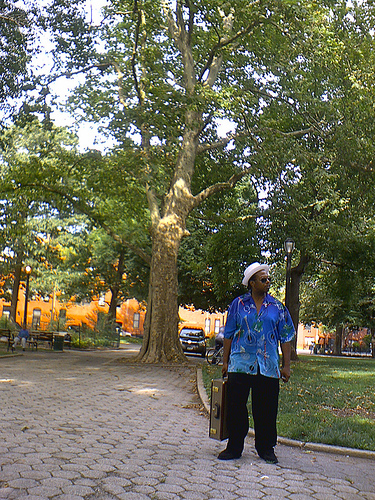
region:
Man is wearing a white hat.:
[229, 258, 276, 278]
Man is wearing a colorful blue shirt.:
[227, 299, 292, 372]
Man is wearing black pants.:
[221, 372, 286, 448]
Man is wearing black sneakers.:
[215, 445, 288, 466]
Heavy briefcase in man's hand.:
[202, 373, 231, 450]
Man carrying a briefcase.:
[206, 262, 293, 469]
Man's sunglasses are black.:
[255, 274, 278, 285]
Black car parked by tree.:
[175, 314, 210, 362]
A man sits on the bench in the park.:
[6, 319, 45, 354]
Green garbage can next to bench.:
[51, 332, 67, 352]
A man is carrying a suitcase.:
[196, 373, 241, 449]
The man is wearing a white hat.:
[239, 262, 277, 281]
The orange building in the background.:
[32, 262, 186, 335]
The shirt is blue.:
[224, 293, 295, 372]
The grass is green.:
[307, 352, 372, 430]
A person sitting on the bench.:
[9, 320, 55, 351]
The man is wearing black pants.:
[222, 366, 289, 440]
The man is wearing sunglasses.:
[255, 275, 277, 283]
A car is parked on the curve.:
[178, 315, 208, 358]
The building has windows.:
[126, 305, 149, 330]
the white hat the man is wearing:
[238, 262, 268, 285]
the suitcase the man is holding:
[209, 373, 223, 442]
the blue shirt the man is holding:
[219, 293, 294, 378]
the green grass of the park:
[198, 349, 374, 444]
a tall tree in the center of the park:
[114, 73, 230, 367]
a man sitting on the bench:
[12, 324, 28, 350]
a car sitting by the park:
[178, 318, 212, 357]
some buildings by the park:
[5, 268, 324, 351]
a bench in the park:
[13, 327, 55, 351]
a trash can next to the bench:
[51, 333, 64, 351]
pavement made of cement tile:
[4, 372, 188, 489]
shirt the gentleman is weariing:
[220, 293, 296, 376]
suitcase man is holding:
[208, 366, 234, 439]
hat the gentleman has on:
[242, 261, 268, 286]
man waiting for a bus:
[202, 260, 297, 464]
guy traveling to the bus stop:
[208, 261, 299, 464]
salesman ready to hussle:
[208, 261, 295, 462]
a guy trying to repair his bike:
[203, 329, 223, 365]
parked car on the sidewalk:
[178, 327, 207, 353]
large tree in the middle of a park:
[135, 149, 197, 362]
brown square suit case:
[208, 377, 225, 442]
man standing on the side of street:
[204, 261, 295, 462]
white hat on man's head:
[241, 260, 269, 285]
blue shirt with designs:
[222, 290, 297, 378]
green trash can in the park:
[51, 334, 64, 350]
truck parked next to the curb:
[176, 325, 209, 356]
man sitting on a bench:
[11, 324, 30, 352]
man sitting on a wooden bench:
[7, 322, 37, 350]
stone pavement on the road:
[0, 366, 195, 498]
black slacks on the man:
[223, 373, 279, 452]